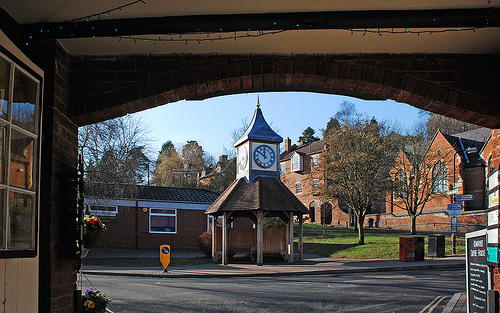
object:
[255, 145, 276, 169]
face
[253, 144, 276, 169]
clock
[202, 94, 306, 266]
gazebo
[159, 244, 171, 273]
sign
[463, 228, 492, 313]
sign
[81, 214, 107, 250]
flowers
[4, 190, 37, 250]
window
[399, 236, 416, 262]
box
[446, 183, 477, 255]
signs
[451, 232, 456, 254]
pole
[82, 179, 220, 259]
building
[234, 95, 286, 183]
tower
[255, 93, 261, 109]
spire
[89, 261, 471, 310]
road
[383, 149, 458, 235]
tree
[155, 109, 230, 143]
sky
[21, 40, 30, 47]
lights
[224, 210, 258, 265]
archway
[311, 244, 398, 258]
grass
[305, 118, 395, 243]
tree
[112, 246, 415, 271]
sidewalk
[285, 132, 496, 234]
building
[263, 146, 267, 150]
numbers